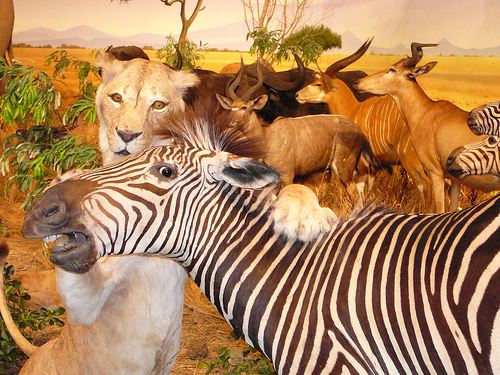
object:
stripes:
[387, 98, 395, 145]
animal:
[466, 102, 500, 137]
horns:
[325, 36, 374, 78]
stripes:
[364, 214, 404, 374]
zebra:
[21, 96, 500, 363]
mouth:
[25, 231, 89, 256]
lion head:
[91, 48, 200, 157]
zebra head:
[21, 93, 281, 275]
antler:
[248, 94, 268, 109]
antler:
[216, 93, 233, 109]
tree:
[246, 23, 342, 67]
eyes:
[108, 93, 122, 104]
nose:
[25, 201, 68, 225]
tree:
[243, 0, 334, 64]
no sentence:
[325, 60, 375, 130]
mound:
[19, 75, 100, 144]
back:
[329, 151, 365, 218]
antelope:
[215, 57, 386, 220]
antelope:
[295, 36, 432, 215]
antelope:
[351, 42, 500, 215]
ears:
[215, 158, 281, 191]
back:
[392, 147, 434, 214]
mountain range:
[12, 14, 500, 56]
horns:
[404, 42, 439, 67]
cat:
[0, 54, 201, 375]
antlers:
[228, 51, 263, 102]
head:
[295, 73, 336, 105]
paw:
[271, 184, 338, 245]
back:
[340, 193, 500, 255]